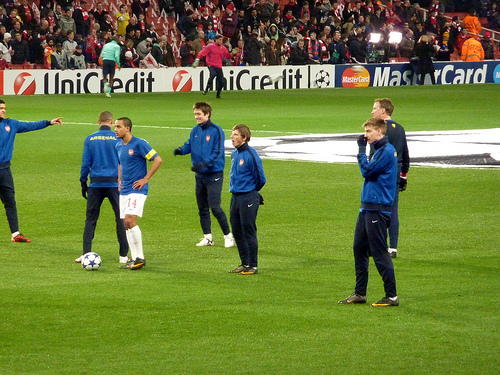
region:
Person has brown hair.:
[374, 85, 391, 113]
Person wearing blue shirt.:
[388, 116, 423, 183]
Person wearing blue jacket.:
[352, 155, 420, 216]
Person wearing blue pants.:
[332, 207, 429, 296]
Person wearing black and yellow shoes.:
[339, 290, 427, 330]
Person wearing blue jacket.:
[231, 154, 268, 175]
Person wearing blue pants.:
[213, 187, 285, 253]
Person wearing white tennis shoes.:
[192, 227, 250, 269]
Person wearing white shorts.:
[119, 188, 168, 230]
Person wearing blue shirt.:
[118, 135, 165, 217]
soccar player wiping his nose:
[345, 117, 422, 326]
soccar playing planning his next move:
[61, 111, 168, 297]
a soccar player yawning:
[224, 120, 269, 287]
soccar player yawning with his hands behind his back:
[214, 122, 286, 294]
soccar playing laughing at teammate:
[171, 96, 229, 268]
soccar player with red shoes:
[1, 83, 68, 265]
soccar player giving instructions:
[0, 92, 72, 276]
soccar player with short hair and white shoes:
[172, 89, 232, 258]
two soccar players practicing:
[92, 23, 239, 98]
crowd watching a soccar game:
[249, 11, 487, 58]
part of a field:
[458, 284, 462, 292]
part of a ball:
[93, 265, 103, 272]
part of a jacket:
[379, 173, 381, 180]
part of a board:
[299, 72, 306, 77]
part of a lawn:
[222, 271, 238, 310]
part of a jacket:
[378, 173, 387, 190]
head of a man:
[373, 116, 381, 133]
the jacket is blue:
[214, 138, 281, 207]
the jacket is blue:
[355, 131, 395, 213]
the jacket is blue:
[62, 124, 131, 190]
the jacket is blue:
[3, 113, 50, 186]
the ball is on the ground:
[75, 243, 112, 279]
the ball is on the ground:
[66, 230, 123, 280]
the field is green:
[155, 231, 280, 349]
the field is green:
[268, 210, 368, 319]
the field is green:
[134, 300, 330, 373]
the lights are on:
[363, 25, 421, 59]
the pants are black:
[198, 180, 285, 292]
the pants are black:
[349, 194, 415, 325]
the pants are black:
[185, 160, 224, 239]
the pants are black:
[82, 175, 134, 270]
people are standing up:
[28, 16, 100, 77]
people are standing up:
[131, 18, 194, 58]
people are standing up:
[173, 16, 364, 71]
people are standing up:
[299, 4, 449, 49]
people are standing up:
[122, 19, 321, 87]